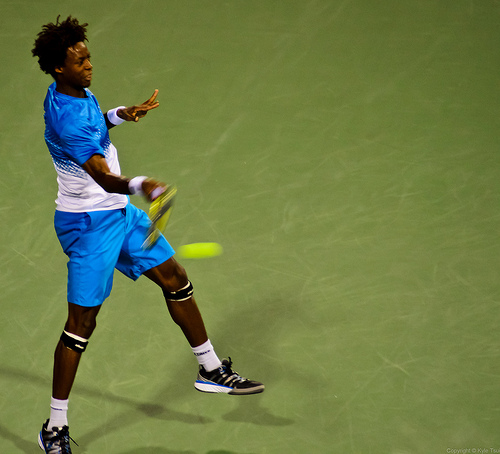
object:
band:
[60, 330, 89, 352]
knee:
[66, 317, 97, 332]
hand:
[120, 88, 160, 123]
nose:
[85, 58, 94, 70]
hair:
[30, 14, 89, 74]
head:
[30, 13, 94, 89]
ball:
[177, 241, 225, 259]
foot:
[192, 363, 264, 395]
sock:
[190, 339, 222, 372]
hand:
[135, 176, 168, 202]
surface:
[245, 131, 424, 351]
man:
[31, 14, 267, 454]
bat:
[139, 183, 178, 253]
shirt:
[43, 82, 131, 214]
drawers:
[53, 202, 175, 308]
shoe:
[193, 356, 265, 396]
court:
[275, 10, 481, 104]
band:
[128, 175, 148, 195]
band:
[106, 106, 126, 127]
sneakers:
[37, 416, 80, 454]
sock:
[45, 396, 70, 431]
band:
[162, 280, 194, 302]